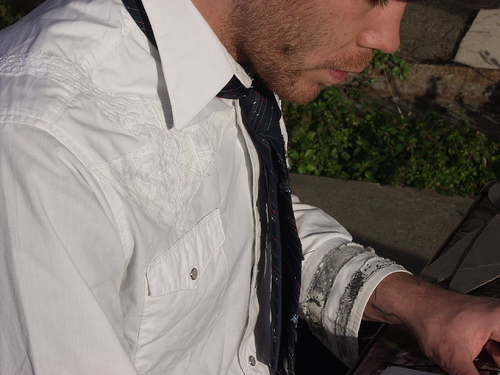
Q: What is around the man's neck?
A: Tie.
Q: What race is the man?
A: White.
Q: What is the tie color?
A: Black.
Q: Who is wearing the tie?
A: The man.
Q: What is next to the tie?
A: Grass.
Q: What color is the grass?
A: Green.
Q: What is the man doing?
A: Playing piano.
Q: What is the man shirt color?
A: White.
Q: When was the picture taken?
A: Daytime.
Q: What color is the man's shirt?
A: White.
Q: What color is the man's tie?
A: Black.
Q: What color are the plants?
A: Green.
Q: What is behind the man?
A: Plants.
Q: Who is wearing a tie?
A: The man.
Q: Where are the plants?
A: Behind the man.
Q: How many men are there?
A: One.